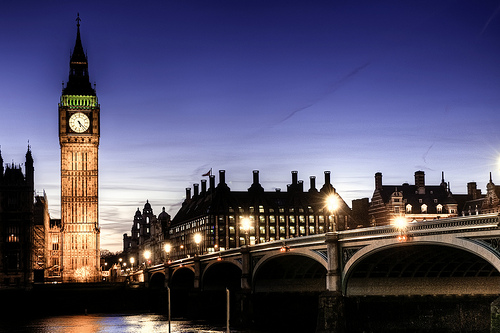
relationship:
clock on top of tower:
[69, 112, 91, 134] [53, 10, 114, 287]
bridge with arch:
[147, 212, 499, 311] [146, 272, 166, 287]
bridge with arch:
[147, 212, 499, 311] [166, 267, 196, 291]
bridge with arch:
[147, 212, 499, 311] [197, 261, 242, 292]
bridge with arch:
[147, 212, 499, 311] [249, 252, 332, 294]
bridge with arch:
[147, 212, 499, 311] [336, 237, 499, 293]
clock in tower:
[67, 112, 92, 133] [56, 8, 101, 283]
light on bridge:
[385, 211, 417, 231] [121, 211, 498, 331]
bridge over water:
[140, 212, 500, 318] [15, 305, 474, 332]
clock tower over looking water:
[60, 12, 100, 280] [8, 315, 216, 331]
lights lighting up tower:
[70, 56, 89, 68] [55, 4, 105, 277]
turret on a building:
[447, 181, 462, 215] [51, 15, 430, 303]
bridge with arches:
[140, 212, 500, 318] [131, 236, 490, 304]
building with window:
[167, 169, 356, 264] [229, 235, 236, 248]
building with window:
[167, 169, 356, 264] [317, 214, 324, 224]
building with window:
[167, 169, 356, 264] [237, 215, 252, 230]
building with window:
[167, 169, 356, 264] [217, 213, 224, 222]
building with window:
[167, 169, 356, 264] [329, 215, 336, 224]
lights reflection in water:
[46, 315, 228, 332] [1, 304, 494, 331]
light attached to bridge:
[322, 188, 347, 231] [125, 246, 497, 306]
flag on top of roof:
[199, 168, 216, 180] [164, 168, 358, 224]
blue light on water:
[100, 315, 124, 328] [55, 315, 80, 325]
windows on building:
[220, 216, 290, 238] [167, 169, 356, 264]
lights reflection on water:
[46, 315, 168, 331] [8, 309, 230, 330]